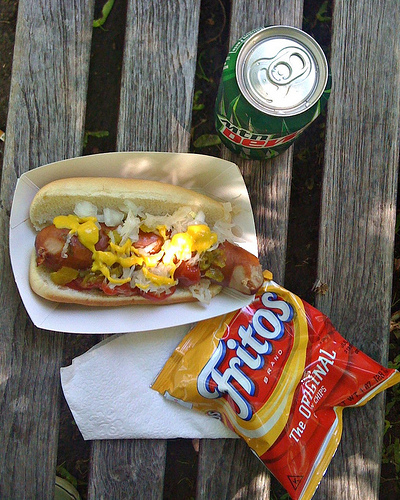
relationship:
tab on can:
[268, 47, 312, 85] [212, 25, 329, 162]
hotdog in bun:
[34, 224, 265, 295] [29, 176, 233, 308]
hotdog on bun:
[34, 224, 265, 295] [29, 176, 233, 308]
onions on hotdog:
[74, 200, 125, 228] [34, 224, 265, 295]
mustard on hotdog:
[52, 214, 216, 286] [34, 224, 265, 295]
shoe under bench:
[55, 476, 82, 499] [0, 2, 399, 500]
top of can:
[236, 24, 329, 119] [212, 25, 329, 162]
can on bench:
[212, 25, 329, 162] [0, 2, 399, 500]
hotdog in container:
[34, 224, 265, 295] [9, 151, 260, 334]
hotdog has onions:
[34, 224, 265, 295] [74, 200, 125, 228]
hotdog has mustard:
[34, 224, 265, 295] [52, 214, 216, 286]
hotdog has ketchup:
[34, 224, 265, 295] [104, 239, 201, 299]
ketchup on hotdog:
[104, 239, 201, 299] [34, 224, 265, 295]